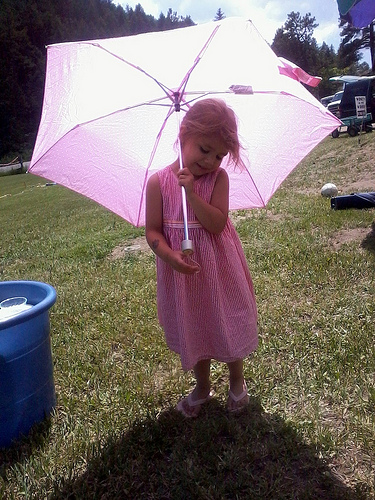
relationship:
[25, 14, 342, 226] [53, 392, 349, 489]
umbrella has shadow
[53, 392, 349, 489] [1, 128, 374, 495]
shadow on grass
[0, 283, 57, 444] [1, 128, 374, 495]
tub on grass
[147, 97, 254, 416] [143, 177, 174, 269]
girl has arm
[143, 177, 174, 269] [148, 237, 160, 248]
arm has fake tattoo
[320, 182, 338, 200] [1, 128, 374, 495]
soccer ball lying in grass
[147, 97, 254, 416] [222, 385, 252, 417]
girl has left flip flop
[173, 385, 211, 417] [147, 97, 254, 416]
right flip flop of a girl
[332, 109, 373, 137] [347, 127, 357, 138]
wagon has wheel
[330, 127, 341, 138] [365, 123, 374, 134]
wagon has wheel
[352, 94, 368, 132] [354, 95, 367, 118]
sign has letters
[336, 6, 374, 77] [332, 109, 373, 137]
tree behind wagon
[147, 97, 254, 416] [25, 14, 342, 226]
girl has umbrella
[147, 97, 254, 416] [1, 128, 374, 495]
girl standing in grass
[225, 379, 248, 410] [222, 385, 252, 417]
foot has left flip flop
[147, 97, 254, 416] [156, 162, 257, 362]
girl wearing sun dress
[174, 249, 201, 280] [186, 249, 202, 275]
hand on loop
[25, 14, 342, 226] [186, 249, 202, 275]
umbrella has at end loop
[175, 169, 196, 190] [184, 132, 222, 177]
hand under face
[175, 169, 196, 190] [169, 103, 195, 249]
hand holding pole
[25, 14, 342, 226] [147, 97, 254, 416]
umbrella behind girl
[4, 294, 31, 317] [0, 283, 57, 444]
cup inside tub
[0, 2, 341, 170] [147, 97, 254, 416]
wall of trees behind girl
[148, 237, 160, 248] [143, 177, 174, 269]
fake tattoo on arm